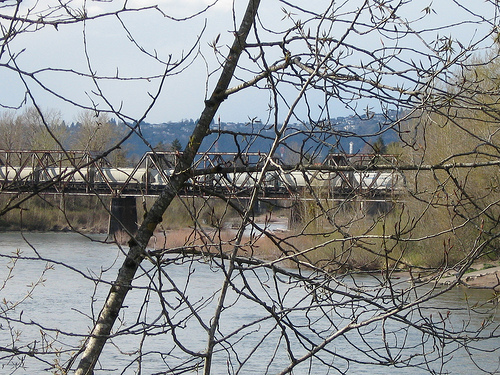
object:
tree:
[56, 0, 352, 375]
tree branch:
[68, 0, 265, 374]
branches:
[29, 75, 119, 116]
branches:
[256, 8, 324, 36]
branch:
[0, 252, 178, 294]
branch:
[218, 57, 298, 100]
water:
[0, 228, 500, 374]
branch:
[194, 127, 275, 141]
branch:
[348, 61, 422, 80]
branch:
[231, 238, 346, 271]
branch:
[120, 226, 214, 334]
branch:
[242, 35, 368, 55]